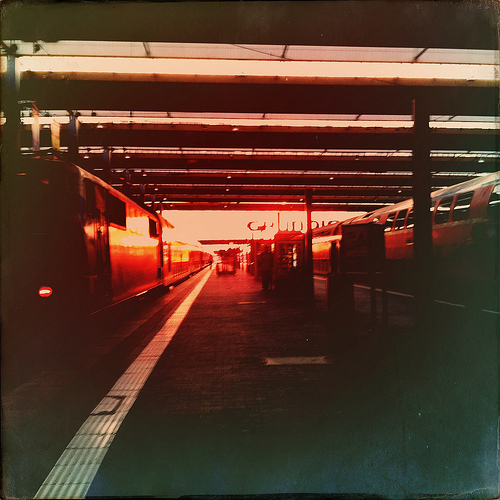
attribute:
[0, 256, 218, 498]
platform — white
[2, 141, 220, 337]
subway — long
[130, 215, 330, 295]
sunset — beautiful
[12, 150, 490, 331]
traffic — slow